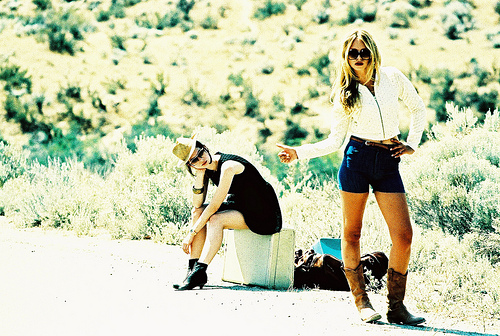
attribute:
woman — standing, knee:
[272, 29, 427, 326]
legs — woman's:
[339, 137, 411, 302]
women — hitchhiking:
[165, 23, 437, 335]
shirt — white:
[289, 66, 432, 158]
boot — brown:
[183, 260, 200, 272]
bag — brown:
[298, 244, 350, 290]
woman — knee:
[296, 13, 462, 328]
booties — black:
[164, 254, 206, 289]